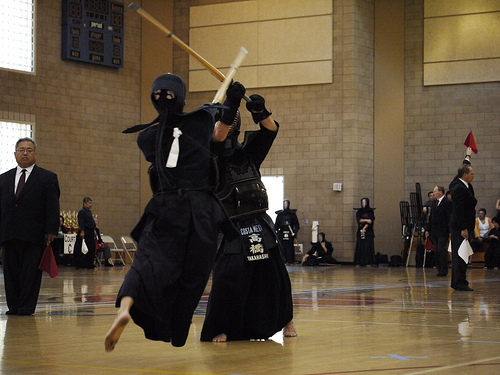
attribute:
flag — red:
[457, 120, 484, 152]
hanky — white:
[456, 236, 475, 266]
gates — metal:
[401, 175, 427, 222]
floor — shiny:
[417, 310, 499, 371]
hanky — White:
[81, 239, 90, 256]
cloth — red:
[456, 126, 486, 161]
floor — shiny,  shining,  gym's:
[10, 261, 492, 371]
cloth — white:
[457, 233, 474, 267]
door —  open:
[264, 176, 283, 225]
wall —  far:
[169, 2, 371, 254]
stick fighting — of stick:
[136, 10, 256, 96]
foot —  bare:
[94, 312, 146, 354]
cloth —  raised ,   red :
[453, 120, 485, 157]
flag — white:
[453, 240, 478, 267]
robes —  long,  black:
[91, 125, 280, 292]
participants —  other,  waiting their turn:
[275, 196, 378, 267]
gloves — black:
[193, 72, 274, 124]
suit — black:
[0, 167, 60, 311]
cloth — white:
[454, 232, 474, 261]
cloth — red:
[39, 239, 72, 283]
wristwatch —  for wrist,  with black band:
[462, 149, 476, 161]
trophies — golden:
[59, 204, 84, 231]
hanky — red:
[462, 122, 489, 156]